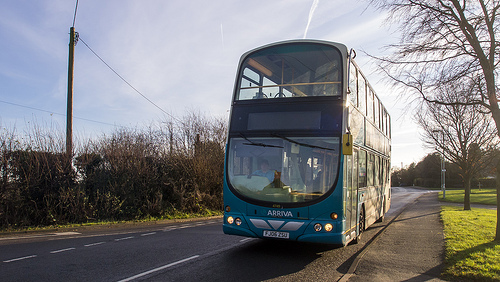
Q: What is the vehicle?
A: Double decker bus.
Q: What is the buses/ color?
A: Blue.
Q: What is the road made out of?
A: Concrete.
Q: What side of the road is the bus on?
A: Right.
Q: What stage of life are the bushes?
A: Dead.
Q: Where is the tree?
A: On the side of the road.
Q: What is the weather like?
A: Scattered clouds.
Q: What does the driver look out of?
A: Wide mirror.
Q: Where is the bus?
A: On the road.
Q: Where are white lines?
A: On the ground.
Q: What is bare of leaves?
A: The trees.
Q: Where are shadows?
A: On the ground.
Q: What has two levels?
A: The bus.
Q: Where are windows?
A: On the bus.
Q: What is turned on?
A: Headlights on the bus.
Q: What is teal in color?
A: Front of the bus.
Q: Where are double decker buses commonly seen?
A: London.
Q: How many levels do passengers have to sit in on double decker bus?
A: Two.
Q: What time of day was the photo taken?
A: Day time.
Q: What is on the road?
A: The bus.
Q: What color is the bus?
A: Blue.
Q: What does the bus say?
A: Arriva.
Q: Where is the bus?
A: The street.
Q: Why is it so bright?
A: Sunny.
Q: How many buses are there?
A: One.